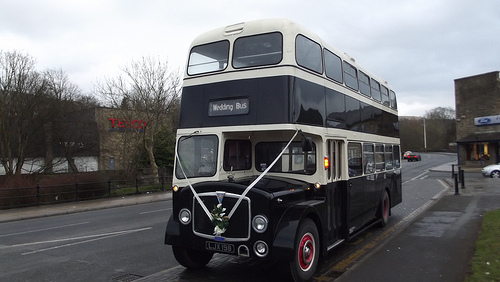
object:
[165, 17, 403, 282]
bus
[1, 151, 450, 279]
road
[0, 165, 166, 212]
railing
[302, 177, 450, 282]
lines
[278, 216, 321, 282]
wheel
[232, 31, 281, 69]
window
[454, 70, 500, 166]
building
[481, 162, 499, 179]
car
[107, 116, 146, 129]
sign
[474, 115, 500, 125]
sign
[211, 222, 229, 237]
flowers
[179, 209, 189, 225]
headlights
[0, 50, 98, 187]
trees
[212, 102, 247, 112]
words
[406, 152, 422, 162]
car